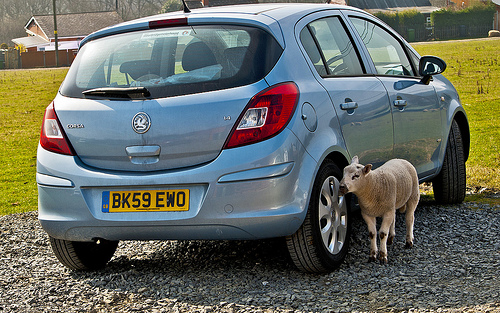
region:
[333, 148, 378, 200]
the head of a lamb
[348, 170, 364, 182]
the eye of a lamb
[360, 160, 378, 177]
the ear of a lamb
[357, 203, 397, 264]
the front legs of a lamb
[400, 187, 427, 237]
the hind leg of a lamb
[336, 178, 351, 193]
the nose of a lamb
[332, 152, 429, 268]
a white lamb on the ground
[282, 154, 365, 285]
a wheel on the car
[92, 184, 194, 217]
a yellow license plate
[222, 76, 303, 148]
a red tail light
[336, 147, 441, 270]
The lamb is white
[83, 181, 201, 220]
Yellow and blue license plate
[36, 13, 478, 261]
The car is blue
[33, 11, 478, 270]
The lamb is next to the car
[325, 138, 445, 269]
The lamb is standing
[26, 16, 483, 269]
The car is parked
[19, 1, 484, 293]
The car is on top of gravel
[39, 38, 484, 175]
Green field behind the car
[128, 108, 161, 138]
White circular logo on back of car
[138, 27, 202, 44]
Long narrow white sticker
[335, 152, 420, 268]
the lamb next to the car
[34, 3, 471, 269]
the parked blue car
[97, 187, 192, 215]
the yellow license plate on the car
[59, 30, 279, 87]
the back window on the blue car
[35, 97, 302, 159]
the lights on the back of the car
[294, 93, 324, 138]
the cover to the gas tank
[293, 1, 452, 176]
the two doors on the right side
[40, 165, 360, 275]
the black back wheels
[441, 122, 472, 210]
the front black wheel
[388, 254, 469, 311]
the rocks on the ground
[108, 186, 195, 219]
Yellow license plate on car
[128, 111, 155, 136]
Silver car logo on back of car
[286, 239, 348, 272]
Black rubber tire on car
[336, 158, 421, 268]
Small baby lamb walking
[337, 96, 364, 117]
Light blue door handle on car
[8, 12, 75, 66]
Brick house in backgroun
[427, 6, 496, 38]
Tall green shrubs in distance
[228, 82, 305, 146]
Red and clear tail light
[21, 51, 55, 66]
Long rusty wooden fence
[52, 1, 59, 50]
Large wooden electrical pole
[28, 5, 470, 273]
a blue four-door car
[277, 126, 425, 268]
sheep standing next to car wheel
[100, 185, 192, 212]
yellow car license plate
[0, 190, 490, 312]
small stones on ground beneath car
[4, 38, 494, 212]
grass covered field in front of car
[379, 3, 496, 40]
hedges forming a wall in front of a building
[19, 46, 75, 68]
a red board fence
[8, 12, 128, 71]
house behind fence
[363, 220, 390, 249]
dark smudges on sheep's knees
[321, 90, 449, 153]
other animals reflected in side of car